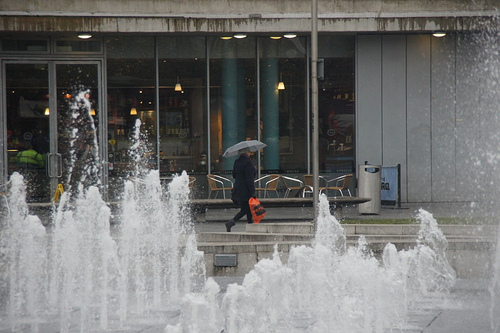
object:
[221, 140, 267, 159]
umbrella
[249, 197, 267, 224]
bag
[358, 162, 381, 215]
trash can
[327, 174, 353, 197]
chair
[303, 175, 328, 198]
chair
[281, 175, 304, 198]
chair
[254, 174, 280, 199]
chair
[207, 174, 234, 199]
chair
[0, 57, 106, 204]
door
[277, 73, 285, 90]
lamp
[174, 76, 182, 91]
lamp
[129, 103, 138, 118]
lamp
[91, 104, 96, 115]
lamp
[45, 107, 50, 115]
lamp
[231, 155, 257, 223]
outfit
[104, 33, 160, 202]
window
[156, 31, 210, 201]
window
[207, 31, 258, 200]
window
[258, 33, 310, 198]
window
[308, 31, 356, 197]
window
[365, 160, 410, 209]
sign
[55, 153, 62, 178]
handle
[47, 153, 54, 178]
handle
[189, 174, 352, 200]
row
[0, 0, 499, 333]
water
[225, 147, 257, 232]
woman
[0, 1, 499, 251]
building